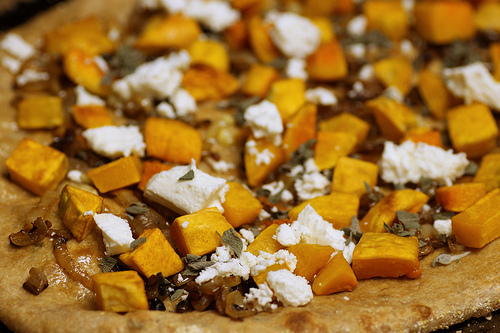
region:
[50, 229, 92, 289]
Visible sliver of onion on the crust.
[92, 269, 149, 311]
Blurry orange piece of cheese closest to the camera by a sliver of onion.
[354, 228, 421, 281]
The largest piece of orange cheese closest to the camera on the right.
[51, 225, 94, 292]
Longest sliver of onion on the left.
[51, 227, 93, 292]
Brownish onion sliver on the left.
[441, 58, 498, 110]
Furthest right chunk of white cheese.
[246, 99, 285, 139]
Middle most triangle shaped white cheese.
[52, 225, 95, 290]
Onion on the left bottom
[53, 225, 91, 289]
Onion sliver on the bottom left.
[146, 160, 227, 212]
Square piece of white cheese with a green speck on it.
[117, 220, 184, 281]
The topping is orange.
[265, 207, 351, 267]
The cheese is white.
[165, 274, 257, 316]
The mushrooms are on the pizza.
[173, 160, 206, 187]
spices are on the cheese.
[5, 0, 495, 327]
The pizza is full of toppings.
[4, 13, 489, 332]
The pizza has a crust.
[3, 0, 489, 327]
The pizza is not cooked.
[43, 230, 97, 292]
The onion is on the pizza.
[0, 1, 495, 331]
The toppings are mixed.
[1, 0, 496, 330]
The pizza has many toppings.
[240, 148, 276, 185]
topping on the pizza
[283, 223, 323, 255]
topping on the pizza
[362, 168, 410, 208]
topping on the pizza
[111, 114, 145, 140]
topping on the pizza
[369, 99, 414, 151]
topping on the pizza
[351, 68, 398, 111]
topping on the pizza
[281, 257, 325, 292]
topping on the pizza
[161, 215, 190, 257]
topping on the pizza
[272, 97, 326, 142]
topping on the pizza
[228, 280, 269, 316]
topping on the pizza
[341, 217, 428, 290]
a piece of carrot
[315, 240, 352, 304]
a piece of carrot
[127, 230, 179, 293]
a piece of carrot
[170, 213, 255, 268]
a piece of carrot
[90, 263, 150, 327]
a piece of carrot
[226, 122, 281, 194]
a piece of carrot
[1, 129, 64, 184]
a piece of carrot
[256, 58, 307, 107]
a piece of carrot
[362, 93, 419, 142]
a piece of carrot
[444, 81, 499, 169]
a piece of carrot